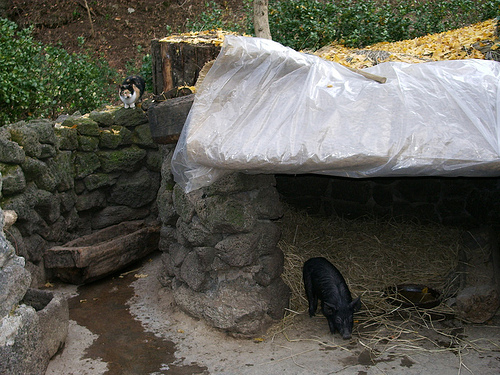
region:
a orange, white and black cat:
[106, 64, 149, 115]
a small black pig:
[289, 254, 366, 351]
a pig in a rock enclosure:
[0, 138, 482, 374]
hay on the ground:
[267, 233, 457, 325]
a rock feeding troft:
[38, 220, 143, 282]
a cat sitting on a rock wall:
[111, 59, 151, 122]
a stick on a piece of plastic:
[327, 57, 405, 89]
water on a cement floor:
[98, 269, 160, 372]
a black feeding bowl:
[388, 270, 450, 308]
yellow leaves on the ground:
[382, 20, 483, 71]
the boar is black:
[293, 250, 372, 344]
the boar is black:
[299, 214, 405, 356]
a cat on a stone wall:
[90, 59, 155, 120]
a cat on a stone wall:
[109, 72, 169, 122]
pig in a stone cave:
[284, 232, 376, 352]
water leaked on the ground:
[71, 288, 192, 368]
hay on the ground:
[383, 293, 450, 350]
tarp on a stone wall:
[200, 49, 484, 181]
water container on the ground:
[38, 208, 175, 298]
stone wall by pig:
[148, 178, 276, 336]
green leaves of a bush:
[5, 14, 105, 113]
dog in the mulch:
[108, 65, 151, 112]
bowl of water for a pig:
[381, 271, 441, 316]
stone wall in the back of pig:
[0, 115, 171, 235]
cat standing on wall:
[112, 71, 147, 127]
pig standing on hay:
[291, 247, 374, 351]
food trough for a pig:
[38, 209, 172, 284]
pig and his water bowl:
[296, 249, 450, 350]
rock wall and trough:
[0, 107, 165, 286]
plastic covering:
[181, 48, 497, 179]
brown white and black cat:
[116, 70, 148, 109]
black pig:
[295, 253, 365, 345]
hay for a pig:
[286, 206, 478, 278]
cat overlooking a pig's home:
[117, 74, 145, 107]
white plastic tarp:
[168, 32, 498, 190]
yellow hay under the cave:
[280, 196, 492, 309]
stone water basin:
[42, 212, 162, 285]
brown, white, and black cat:
[116, 74, 145, 111]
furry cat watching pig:
[116, 73, 144, 108]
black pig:
[302, 250, 362, 342]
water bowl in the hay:
[381, 282, 448, 309]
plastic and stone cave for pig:
[152, 17, 499, 340]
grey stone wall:
[0, 101, 154, 373]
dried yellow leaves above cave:
[335, 17, 497, 64]